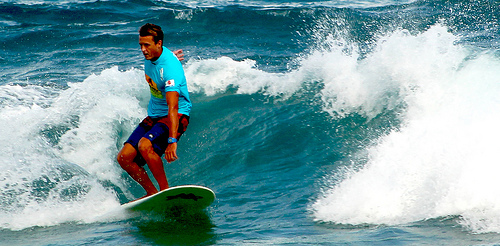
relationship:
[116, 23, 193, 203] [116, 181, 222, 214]
man in surfboard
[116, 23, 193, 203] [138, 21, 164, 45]
man in hair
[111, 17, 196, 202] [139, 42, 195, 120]
man in t-shirt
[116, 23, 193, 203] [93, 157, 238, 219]
man in surfboard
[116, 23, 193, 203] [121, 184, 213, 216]
man in surfboard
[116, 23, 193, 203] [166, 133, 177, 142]
man on blue watch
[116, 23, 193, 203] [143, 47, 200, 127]
man on shirt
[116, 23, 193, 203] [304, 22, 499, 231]
man on wave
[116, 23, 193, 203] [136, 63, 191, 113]
man wearing shirt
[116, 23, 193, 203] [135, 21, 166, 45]
man has hair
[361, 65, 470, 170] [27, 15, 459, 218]
wave in ocean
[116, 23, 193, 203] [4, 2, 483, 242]
man surfing in ocean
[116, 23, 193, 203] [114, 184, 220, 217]
man on surfboard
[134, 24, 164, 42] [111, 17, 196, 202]
hair on man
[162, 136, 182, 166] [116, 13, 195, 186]
hand of man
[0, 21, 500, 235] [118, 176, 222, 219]
wave behind surfboard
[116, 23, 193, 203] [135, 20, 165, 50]
man with hair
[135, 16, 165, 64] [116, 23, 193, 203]
head of man